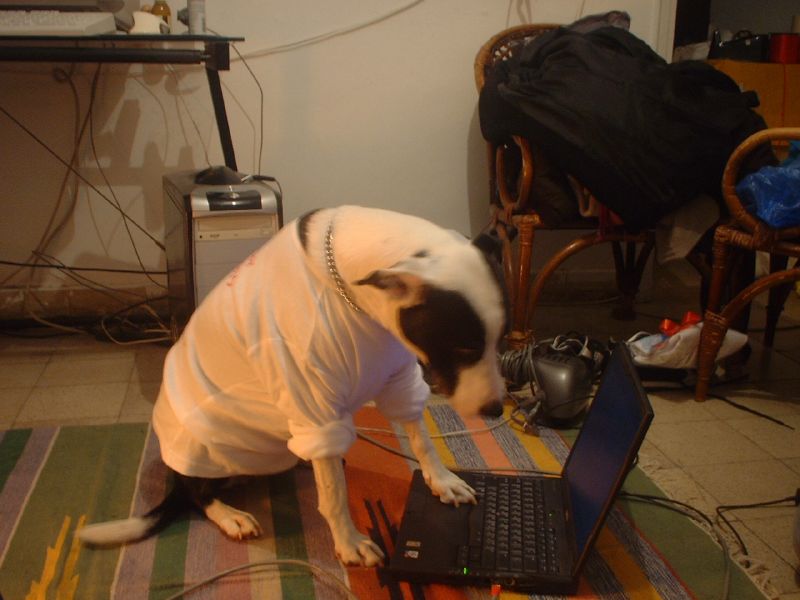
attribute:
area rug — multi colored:
[3, 386, 779, 596]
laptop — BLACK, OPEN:
[403, 343, 654, 558]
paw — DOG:
[394, 442, 469, 507]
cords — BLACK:
[659, 482, 704, 531]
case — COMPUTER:
[166, 164, 266, 268]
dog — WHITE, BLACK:
[114, 219, 514, 536]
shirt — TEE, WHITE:
[176, 298, 330, 447]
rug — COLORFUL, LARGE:
[51, 445, 112, 504]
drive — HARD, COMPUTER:
[184, 171, 255, 255]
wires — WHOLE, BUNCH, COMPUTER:
[45, 199, 146, 335]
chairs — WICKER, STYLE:
[498, 33, 775, 369]